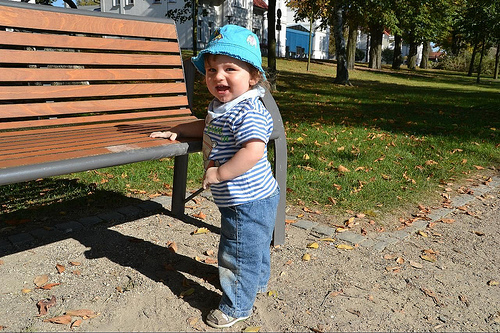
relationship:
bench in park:
[2, 1, 289, 265] [1, 0, 500, 253]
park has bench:
[1, 0, 500, 253] [2, 1, 289, 265]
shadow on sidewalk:
[1, 116, 225, 325] [2, 172, 500, 333]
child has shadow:
[147, 20, 284, 331] [1, 116, 225, 325]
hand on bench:
[147, 126, 184, 142] [2, 1, 289, 265]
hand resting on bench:
[147, 126, 184, 142] [2, 1, 289, 265]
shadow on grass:
[1, 179, 169, 258] [1, 146, 207, 244]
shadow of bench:
[1, 179, 169, 258] [2, 1, 289, 265]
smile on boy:
[210, 83, 233, 95] [147, 20, 284, 331]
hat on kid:
[190, 22, 269, 81] [147, 20, 284, 331]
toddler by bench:
[147, 20, 284, 331] [2, 1, 289, 265]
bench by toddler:
[2, 1, 289, 265] [147, 20, 284, 331]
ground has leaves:
[3, 53, 499, 333] [1, 76, 500, 327]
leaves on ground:
[1, 76, 500, 327] [3, 53, 499, 333]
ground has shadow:
[3, 53, 499, 333] [1, 116, 225, 325]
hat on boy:
[190, 22, 269, 81] [147, 20, 284, 331]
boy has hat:
[147, 20, 284, 331] [190, 22, 269, 81]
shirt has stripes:
[200, 94, 280, 210] [211, 96, 284, 204]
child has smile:
[147, 20, 284, 331] [210, 83, 233, 95]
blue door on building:
[285, 30, 315, 61] [285, 17, 334, 63]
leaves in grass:
[482, 278, 500, 289] [0, 34, 499, 250]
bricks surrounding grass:
[1, 171, 497, 261] [0, 34, 499, 250]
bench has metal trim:
[2, 1, 289, 265] [0, 0, 292, 254]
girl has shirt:
[147, 20, 284, 331] [200, 94, 280, 210]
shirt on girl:
[200, 94, 280, 210] [147, 20, 284, 331]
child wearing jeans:
[147, 20, 284, 331] [214, 185, 283, 319]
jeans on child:
[214, 185, 283, 319] [147, 20, 284, 331]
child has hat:
[147, 20, 284, 331] [190, 22, 269, 81]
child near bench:
[147, 20, 284, 331] [2, 1, 289, 265]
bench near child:
[2, 1, 289, 265] [147, 20, 284, 331]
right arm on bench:
[148, 118, 211, 145] [2, 1, 289, 265]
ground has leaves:
[3, 53, 499, 333] [482, 278, 500, 289]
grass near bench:
[0, 34, 499, 250] [2, 1, 289, 265]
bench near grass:
[2, 1, 289, 265] [0, 34, 499, 250]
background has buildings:
[98, 3, 498, 74] [103, 1, 426, 67]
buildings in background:
[103, 1, 426, 67] [98, 3, 498, 74]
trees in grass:
[185, 1, 499, 95] [0, 34, 499, 250]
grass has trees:
[0, 34, 499, 250] [185, 1, 499, 95]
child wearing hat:
[147, 20, 284, 331] [190, 22, 269, 81]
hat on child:
[190, 22, 269, 81] [147, 20, 284, 331]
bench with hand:
[2, 1, 289, 265] [147, 126, 184, 142]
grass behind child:
[0, 34, 499, 250] [147, 20, 284, 331]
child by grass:
[147, 20, 284, 331] [0, 34, 499, 250]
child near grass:
[147, 20, 284, 331] [0, 34, 499, 250]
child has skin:
[147, 20, 284, 331] [148, 53, 281, 193]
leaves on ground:
[482, 278, 500, 289] [3, 53, 499, 333]